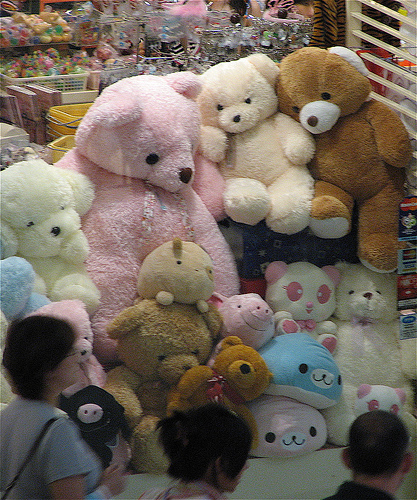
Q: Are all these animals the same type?
A: Yes, all the animals are bears.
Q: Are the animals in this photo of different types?
A: No, all the animals are bears.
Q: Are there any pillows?
A: No, there are no pillows.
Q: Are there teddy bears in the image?
A: Yes, there is a teddy bear.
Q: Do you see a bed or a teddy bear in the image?
A: Yes, there is a teddy bear.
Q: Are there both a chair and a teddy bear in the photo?
A: No, there is a teddy bear but no chairs.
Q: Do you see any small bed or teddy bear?
A: Yes, there is a small teddy bear.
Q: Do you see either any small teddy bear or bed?
A: Yes, there is a small teddy bear.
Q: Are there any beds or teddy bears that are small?
A: Yes, the teddy bear is small.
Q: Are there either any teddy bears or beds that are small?
A: Yes, the teddy bear is small.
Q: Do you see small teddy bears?
A: Yes, there is a small teddy bear.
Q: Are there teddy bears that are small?
A: Yes, there is a teddy bear that is small.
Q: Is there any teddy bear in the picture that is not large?
A: Yes, there is a small teddy bear.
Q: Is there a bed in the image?
A: No, there are no beds.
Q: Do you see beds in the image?
A: No, there are no beds.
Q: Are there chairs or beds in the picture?
A: No, there are no beds or chairs.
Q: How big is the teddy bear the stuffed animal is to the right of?
A: The teddy bear is small.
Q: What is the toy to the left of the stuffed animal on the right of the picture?
A: The toy is a teddy bear.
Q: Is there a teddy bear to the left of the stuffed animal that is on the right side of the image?
A: Yes, there is a teddy bear to the left of the stuffed animal.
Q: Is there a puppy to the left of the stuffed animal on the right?
A: No, there is a teddy bear to the left of the stuffed animal.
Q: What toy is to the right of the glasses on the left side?
A: The toy is a teddy bear.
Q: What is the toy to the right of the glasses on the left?
A: The toy is a teddy bear.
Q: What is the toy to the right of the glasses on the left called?
A: The toy is a teddy bear.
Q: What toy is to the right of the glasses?
A: The toy is a teddy bear.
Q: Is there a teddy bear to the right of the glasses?
A: Yes, there is a teddy bear to the right of the glasses.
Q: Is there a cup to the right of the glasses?
A: No, there is a teddy bear to the right of the glasses.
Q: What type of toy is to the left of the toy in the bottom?
A: The toy is a teddy bear.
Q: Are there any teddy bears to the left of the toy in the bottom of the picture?
A: Yes, there is a teddy bear to the left of the toy.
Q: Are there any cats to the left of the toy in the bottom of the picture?
A: No, there is a teddy bear to the left of the toy.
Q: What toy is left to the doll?
A: The toy is a teddy bear.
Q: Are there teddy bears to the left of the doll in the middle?
A: Yes, there is a teddy bear to the left of the doll.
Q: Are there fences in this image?
A: No, there are no fences.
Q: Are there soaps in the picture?
A: No, there are no soaps.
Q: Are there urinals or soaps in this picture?
A: No, there are no soaps or urinals.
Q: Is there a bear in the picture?
A: Yes, there is a bear.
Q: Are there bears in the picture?
A: Yes, there is a bear.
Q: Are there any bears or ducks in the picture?
A: Yes, there is a bear.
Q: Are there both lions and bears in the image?
A: No, there is a bear but no lions.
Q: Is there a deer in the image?
A: No, there is no deer.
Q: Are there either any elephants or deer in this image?
A: No, there are no deer or elephants.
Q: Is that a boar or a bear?
A: That is a bear.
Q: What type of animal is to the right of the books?
A: The animal is a bear.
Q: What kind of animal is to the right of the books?
A: The animal is a bear.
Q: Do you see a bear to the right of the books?
A: Yes, there is a bear to the right of the books.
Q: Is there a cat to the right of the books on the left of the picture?
A: No, there is a bear to the right of the books.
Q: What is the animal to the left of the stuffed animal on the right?
A: The animal is a bear.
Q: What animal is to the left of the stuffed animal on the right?
A: The animal is a bear.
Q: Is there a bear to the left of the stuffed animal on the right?
A: Yes, there is a bear to the left of the stuffed animal.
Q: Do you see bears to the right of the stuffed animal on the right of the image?
A: No, the bear is to the left of the stuffed animal.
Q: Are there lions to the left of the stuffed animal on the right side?
A: No, there is a bear to the left of the stuffed animal.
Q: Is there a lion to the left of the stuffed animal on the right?
A: No, there is a bear to the left of the stuffed animal.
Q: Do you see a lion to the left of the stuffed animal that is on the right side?
A: No, there is a bear to the left of the stuffed animal.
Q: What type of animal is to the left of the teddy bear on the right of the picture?
A: The animal is a bear.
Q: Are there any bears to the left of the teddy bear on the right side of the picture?
A: Yes, there is a bear to the left of the teddy bear.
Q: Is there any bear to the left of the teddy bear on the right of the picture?
A: Yes, there is a bear to the left of the teddy bear.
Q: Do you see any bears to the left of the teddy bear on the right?
A: Yes, there is a bear to the left of the teddy bear.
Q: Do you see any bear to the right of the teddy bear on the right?
A: No, the bear is to the left of the teddy bear.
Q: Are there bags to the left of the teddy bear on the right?
A: No, there is a bear to the left of the teddy bear.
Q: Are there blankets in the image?
A: No, there are no blankets.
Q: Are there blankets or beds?
A: No, there are no blankets or beds.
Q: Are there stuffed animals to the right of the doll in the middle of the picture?
A: Yes, there is a stuffed animal to the right of the doll.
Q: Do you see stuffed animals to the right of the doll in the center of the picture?
A: Yes, there is a stuffed animal to the right of the doll.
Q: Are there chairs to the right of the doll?
A: No, there is a stuffed animal to the right of the doll.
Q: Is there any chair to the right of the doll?
A: No, there is a stuffed animal to the right of the doll.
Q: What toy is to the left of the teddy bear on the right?
A: The toy is a stuffed animal.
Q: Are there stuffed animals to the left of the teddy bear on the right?
A: Yes, there is a stuffed animal to the left of the teddy bear.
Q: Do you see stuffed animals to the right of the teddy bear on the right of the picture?
A: No, the stuffed animal is to the left of the teddy bear.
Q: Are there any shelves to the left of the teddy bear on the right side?
A: No, there is a stuffed animal to the left of the teddy bear.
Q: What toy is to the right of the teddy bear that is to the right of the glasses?
A: The toy is a stuffed animal.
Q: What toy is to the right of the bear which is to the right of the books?
A: The toy is a stuffed animal.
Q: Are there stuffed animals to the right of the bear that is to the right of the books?
A: Yes, there is a stuffed animal to the right of the bear.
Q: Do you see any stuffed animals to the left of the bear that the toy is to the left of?
A: No, the stuffed animal is to the right of the bear.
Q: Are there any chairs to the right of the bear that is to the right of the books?
A: No, there is a stuffed animal to the right of the bear.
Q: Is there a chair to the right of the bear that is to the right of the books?
A: No, there is a stuffed animal to the right of the bear.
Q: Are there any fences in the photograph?
A: No, there are no fences.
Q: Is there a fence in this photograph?
A: No, there are no fences.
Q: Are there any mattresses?
A: No, there are no mattresses.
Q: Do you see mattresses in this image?
A: No, there are no mattresses.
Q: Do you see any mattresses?
A: No, there are no mattresses.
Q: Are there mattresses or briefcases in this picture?
A: No, there are no mattresses or briefcases.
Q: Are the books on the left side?
A: Yes, the books are on the left of the image.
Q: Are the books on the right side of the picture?
A: No, the books are on the left of the image.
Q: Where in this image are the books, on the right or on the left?
A: The books are on the left of the image.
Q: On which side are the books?
A: The books are on the left of the image.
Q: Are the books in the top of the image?
A: Yes, the books are in the top of the image.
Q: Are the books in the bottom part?
A: No, the books are in the top of the image.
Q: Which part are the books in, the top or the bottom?
A: The books are in the top of the image.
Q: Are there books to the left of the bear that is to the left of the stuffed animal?
A: Yes, there are books to the left of the bear.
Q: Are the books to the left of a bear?
A: Yes, the books are to the left of a bear.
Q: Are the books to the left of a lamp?
A: No, the books are to the left of a bear.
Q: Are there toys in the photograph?
A: Yes, there is a toy.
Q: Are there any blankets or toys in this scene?
A: Yes, there is a toy.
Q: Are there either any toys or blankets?
A: Yes, there is a toy.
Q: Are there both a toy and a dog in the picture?
A: No, there is a toy but no dogs.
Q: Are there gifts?
A: No, there are no gifts.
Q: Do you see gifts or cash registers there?
A: No, there are no gifts or cash registers.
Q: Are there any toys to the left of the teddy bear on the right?
A: Yes, there is a toy to the left of the teddy bear.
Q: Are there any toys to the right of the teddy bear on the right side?
A: No, the toy is to the left of the teddy bear.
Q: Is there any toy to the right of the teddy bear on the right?
A: No, the toy is to the left of the teddy bear.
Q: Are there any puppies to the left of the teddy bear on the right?
A: No, there is a toy to the left of the teddy bear.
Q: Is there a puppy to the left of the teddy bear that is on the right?
A: No, there is a toy to the left of the teddy bear.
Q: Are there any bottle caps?
A: No, there are no bottle caps.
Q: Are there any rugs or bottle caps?
A: No, there are no bottle caps or rugs.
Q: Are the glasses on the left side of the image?
A: Yes, the glasses are on the left of the image.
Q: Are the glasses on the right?
A: No, the glasses are on the left of the image.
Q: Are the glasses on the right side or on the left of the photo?
A: The glasses are on the left of the image.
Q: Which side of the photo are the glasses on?
A: The glasses are on the left of the image.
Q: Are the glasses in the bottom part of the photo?
A: Yes, the glasses are in the bottom of the image.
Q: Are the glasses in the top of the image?
A: No, the glasses are in the bottom of the image.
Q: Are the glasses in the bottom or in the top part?
A: The glasses are in the bottom of the image.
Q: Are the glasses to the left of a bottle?
A: No, the glasses are to the left of the teddy bear.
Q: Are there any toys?
A: Yes, there is a toy.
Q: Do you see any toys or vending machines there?
A: Yes, there is a toy.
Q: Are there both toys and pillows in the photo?
A: No, there is a toy but no pillows.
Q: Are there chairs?
A: No, there are no chairs.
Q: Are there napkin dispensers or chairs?
A: No, there are no chairs or napkin dispensers.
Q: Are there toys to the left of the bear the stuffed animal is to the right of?
A: Yes, there is a toy to the left of the bear.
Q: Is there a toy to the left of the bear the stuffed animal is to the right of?
A: Yes, there is a toy to the left of the bear.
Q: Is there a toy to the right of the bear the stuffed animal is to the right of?
A: No, the toy is to the left of the bear.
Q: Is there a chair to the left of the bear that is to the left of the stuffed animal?
A: No, there is a toy to the left of the bear.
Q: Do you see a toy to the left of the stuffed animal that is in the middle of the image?
A: Yes, there is a toy to the left of the stuffed animal.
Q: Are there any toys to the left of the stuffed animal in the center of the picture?
A: Yes, there is a toy to the left of the stuffed animal.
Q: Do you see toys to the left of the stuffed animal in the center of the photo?
A: Yes, there is a toy to the left of the stuffed animal.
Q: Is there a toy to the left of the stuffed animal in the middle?
A: Yes, there is a toy to the left of the stuffed animal.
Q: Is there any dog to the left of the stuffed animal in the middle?
A: No, there is a toy to the left of the stuffed animal.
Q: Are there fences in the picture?
A: No, there are no fences.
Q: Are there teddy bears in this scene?
A: Yes, there is a teddy bear.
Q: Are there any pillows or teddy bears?
A: Yes, there is a teddy bear.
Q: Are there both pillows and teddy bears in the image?
A: No, there is a teddy bear but no pillows.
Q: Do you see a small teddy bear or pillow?
A: Yes, there is a small teddy bear.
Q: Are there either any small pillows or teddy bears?
A: Yes, there is a small teddy bear.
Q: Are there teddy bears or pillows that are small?
A: Yes, the teddy bear is small.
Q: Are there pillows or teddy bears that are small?
A: Yes, the teddy bear is small.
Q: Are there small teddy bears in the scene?
A: Yes, there is a small teddy bear.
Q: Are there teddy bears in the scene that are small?
A: Yes, there is a teddy bear that is small.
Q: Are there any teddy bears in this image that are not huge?
A: Yes, there is a small teddy bear.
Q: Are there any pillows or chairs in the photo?
A: No, there are no chairs or pillows.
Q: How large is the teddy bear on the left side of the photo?
A: The teddy bear is small.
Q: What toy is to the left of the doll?
A: The toy is a teddy bear.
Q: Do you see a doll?
A: Yes, there is a doll.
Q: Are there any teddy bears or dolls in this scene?
A: Yes, there is a doll.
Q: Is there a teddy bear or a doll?
A: Yes, there is a doll.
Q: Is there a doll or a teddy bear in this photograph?
A: Yes, there is a doll.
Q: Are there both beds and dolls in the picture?
A: No, there is a doll but no beds.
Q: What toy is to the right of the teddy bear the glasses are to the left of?
A: The toy is a doll.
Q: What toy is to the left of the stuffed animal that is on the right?
A: The toy is a doll.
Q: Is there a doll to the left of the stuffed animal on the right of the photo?
A: Yes, there is a doll to the left of the stuffed animal.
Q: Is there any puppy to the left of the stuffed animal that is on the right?
A: No, there is a doll to the left of the stuffed animal.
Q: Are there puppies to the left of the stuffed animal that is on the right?
A: No, there is a doll to the left of the stuffed animal.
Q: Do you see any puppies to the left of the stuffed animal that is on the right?
A: No, there is a doll to the left of the stuffed animal.